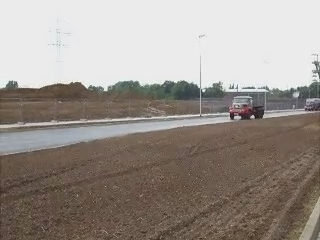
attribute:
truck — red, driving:
[229, 96, 267, 121]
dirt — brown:
[2, 113, 320, 239]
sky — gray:
[2, 3, 320, 91]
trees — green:
[87, 79, 224, 100]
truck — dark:
[304, 101, 320, 112]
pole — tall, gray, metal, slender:
[197, 35, 204, 119]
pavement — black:
[1, 107, 320, 160]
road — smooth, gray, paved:
[2, 109, 320, 157]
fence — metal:
[0, 95, 319, 126]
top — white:
[220, 88, 268, 95]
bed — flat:
[253, 102, 268, 114]